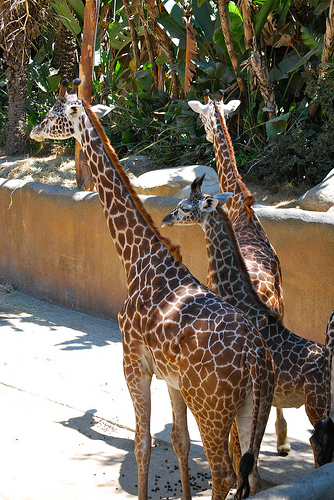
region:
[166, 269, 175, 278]
spot on the giraffe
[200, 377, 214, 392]
spot on the giraffe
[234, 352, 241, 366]
spot on the giraffe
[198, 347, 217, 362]
spot on the giraffe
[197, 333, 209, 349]
spot on the giraffe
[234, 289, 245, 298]
spot on the giraffe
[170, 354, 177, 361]
spot on the giraffe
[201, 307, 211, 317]
spot on the giraffe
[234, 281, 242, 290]
spot on the giraffe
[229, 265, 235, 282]
spot on the giraffe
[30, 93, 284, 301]
giraffes standing in the corner of the enclosure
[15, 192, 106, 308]
cement wall of the enclosure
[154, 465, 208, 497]
black rocks on the ground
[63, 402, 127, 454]
shadow of the giraffe on the ground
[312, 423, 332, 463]
long black hair at the end of the giraffe's tail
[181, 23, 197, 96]
dead leaf hanging down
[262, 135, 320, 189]
small bush at the top of the wall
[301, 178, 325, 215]
large rock behind the wall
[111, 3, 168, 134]
trees growing behind the wall of the enclosure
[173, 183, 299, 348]
young giraffe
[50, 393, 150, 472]
shadow of the giraffe on the ground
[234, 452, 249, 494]
black hair at the end of the tail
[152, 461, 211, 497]
black stones on the ground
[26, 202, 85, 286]
cement wall of the enclosure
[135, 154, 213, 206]
large rock behind the cement wall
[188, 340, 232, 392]
spots on the giraffe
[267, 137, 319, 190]
bush growing behind the wall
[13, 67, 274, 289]
three giraffes together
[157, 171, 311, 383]
younger giraffe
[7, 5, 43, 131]
tree behind the wall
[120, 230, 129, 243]
spot on the giraffe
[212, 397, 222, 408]
spot on the giraffe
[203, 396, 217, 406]
spot on the giraffe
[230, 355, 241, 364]
spot on the giraffe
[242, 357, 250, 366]
spot on the giraffe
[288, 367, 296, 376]
spot on the giraffe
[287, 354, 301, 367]
spot on the giraffe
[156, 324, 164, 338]
spot on the giraffe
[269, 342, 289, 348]
spot on the giraffe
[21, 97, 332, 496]
three giraffes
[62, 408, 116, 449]
the shadow of the giraffe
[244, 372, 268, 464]
the tail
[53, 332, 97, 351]
a shadow on the ground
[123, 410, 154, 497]
the giraffes leg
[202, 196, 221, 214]
ear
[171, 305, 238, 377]
pattern of the giraffe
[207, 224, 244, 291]
the neck of the giraffe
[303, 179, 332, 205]
a big rock on the ground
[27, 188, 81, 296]
a wall